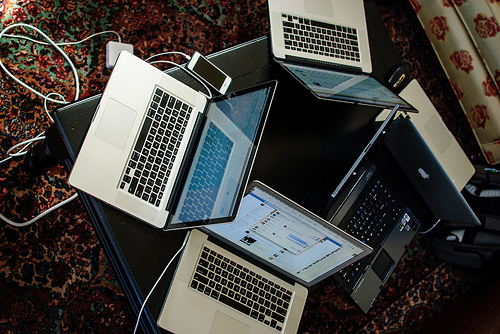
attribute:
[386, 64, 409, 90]
computer mouse — black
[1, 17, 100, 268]
cords — white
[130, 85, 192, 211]
keys — black 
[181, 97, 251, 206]
screen — black